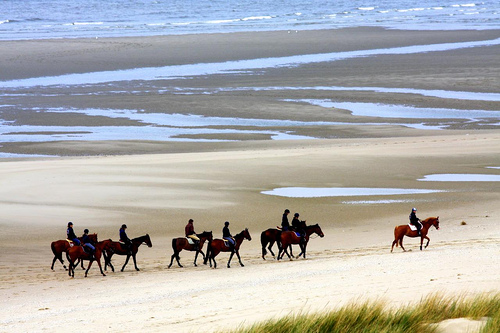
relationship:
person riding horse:
[118, 222, 134, 254] [98, 233, 153, 271]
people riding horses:
[50, 206, 426, 258] [231, 198, 353, 277]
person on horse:
[292, 211, 306, 240] [257, 224, 305, 259]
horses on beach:
[13, 177, 464, 293] [10, 157, 497, 327]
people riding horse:
[407, 206, 422, 235] [396, 220, 436, 248]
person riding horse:
[292, 211, 306, 240] [275, 223, 326, 255]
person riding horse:
[118, 222, 134, 254] [209, 240, 252, 270]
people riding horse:
[407, 206, 422, 235] [251, 224, 321, 252]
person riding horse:
[220, 218, 239, 251] [207, 220, 253, 269]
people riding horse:
[407, 206, 422, 235] [169, 232, 233, 274]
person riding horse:
[65, 222, 76, 245] [62, 238, 114, 276]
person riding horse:
[65, 222, 80, 244] [102, 231, 154, 269]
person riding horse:
[118, 222, 134, 254] [166, 228, 213, 265]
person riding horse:
[65, 222, 80, 244] [258, 217, 304, 262]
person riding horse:
[292, 211, 306, 240] [284, 223, 323, 258]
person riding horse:
[292, 211, 306, 240] [388, 215, 440, 252]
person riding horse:
[293, 211, 305, 240] [213, 227, 248, 267]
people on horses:
[407, 206, 422, 235] [49, 205, 440, 279]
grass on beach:
[244, 289, 491, 331] [39, 46, 414, 299]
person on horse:
[65, 222, 80, 244] [38, 220, 105, 262]